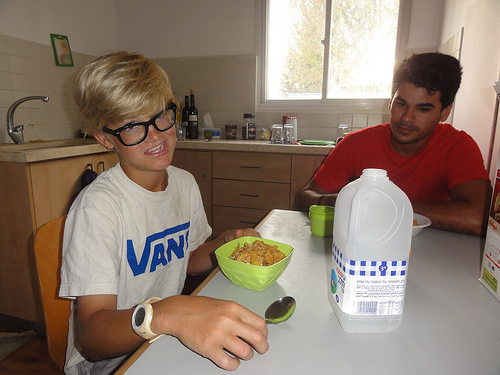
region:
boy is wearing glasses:
[50, 50, 282, 373]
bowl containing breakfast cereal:
[205, 228, 302, 289]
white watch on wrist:
[117, 291, 206, 344]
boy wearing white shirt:
[44, 47, 267, 362]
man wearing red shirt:
[293, 42, 487, 232]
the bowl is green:
[204, 225, 297, 292]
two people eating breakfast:
[52, 40, 486, 354]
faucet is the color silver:
[3, 88, 60, 148]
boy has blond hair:
[62, 38, 205, 182]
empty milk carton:
[317, 164, 419, 346]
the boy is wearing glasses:
[91, 99, 180, 148]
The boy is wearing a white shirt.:
[56, 159, 216, 374]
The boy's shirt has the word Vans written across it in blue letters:
[125, 217, 191, 276]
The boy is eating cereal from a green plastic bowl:
[212, 232, 297, 294]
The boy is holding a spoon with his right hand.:
[254, 292, 298, 327]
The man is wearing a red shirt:
[298, 49, 493, 239]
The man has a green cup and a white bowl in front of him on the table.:
[307, 202, 435, 239]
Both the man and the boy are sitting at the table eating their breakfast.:
[55, 26, 491, 372]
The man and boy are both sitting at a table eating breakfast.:
[105, 205, 495, 370]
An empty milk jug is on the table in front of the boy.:
[325, 161, 410, 336]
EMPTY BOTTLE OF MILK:
[319, 163, 417, 337]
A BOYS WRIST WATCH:
[123, 291, 183, 343]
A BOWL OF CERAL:
[205, 228, 299, 296]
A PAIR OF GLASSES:
[100, 98, 184, 148]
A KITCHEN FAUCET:
[4, 90, 59, 150]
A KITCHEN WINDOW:
[236, 1, 414, 115]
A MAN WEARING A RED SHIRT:
[296, 49, 495, 229]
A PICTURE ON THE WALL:
[44, 23, 79, 76]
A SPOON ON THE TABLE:
[256, 291, 307, 331]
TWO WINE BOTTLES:
[178, 86, 207, 145]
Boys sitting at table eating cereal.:
[57, 51, 495, 366]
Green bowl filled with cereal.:
[213, 236, 301, 295]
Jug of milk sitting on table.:
[322, 171, 429, 339]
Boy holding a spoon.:
[213, 288, 304, 369]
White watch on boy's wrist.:
[127, 296, 161, 342]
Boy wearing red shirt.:
[312, 123, 485, 212]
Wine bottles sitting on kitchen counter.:
[179, 91, 204, 142]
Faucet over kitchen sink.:
[1, 93, 64, 152]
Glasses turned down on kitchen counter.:
[263, 120, 305, 149]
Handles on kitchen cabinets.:
[230, 163, 271, 228]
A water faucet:
[5, 82, 52, 142]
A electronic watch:
[128, 302, 172, 339]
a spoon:
[261, 299, 301, 321]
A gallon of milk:
[330, 152, 406, 335]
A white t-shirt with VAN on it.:
[72, 181, 206, 301]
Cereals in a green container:
[210, 237, 300, 279]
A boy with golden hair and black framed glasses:
[70, 54, 185, 174]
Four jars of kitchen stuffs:
[237, 102, 312, 142]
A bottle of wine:
[184, 84, 204, 141]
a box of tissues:
[194, 112, 226, 139]